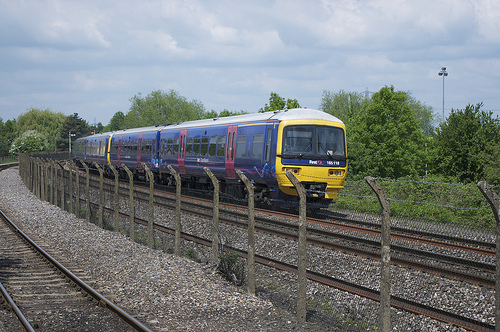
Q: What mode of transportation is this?
A: Train.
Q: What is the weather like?
A: Partly cloudy.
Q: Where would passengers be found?
A: Train cars.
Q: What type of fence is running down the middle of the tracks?
A: Chain link with barbed wire.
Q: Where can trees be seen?
A: Background.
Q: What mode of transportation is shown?
A: Train.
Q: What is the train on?
A: Tracks.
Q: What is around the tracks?
A: Gravel.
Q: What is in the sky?
A: Clouds.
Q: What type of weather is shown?
A: Cloudy.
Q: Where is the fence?
A: Between the tracks.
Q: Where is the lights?
A: Pole.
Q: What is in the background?
A: Trees.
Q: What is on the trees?
A: Leaves.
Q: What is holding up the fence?
A: Curved poles.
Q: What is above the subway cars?
A: Slightly cloudy skies.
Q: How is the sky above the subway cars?
A: White and blue.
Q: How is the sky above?
A: White and blue.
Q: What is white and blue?
A: The sky.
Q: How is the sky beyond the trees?
A: White and blue.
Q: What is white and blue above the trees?
A: The sky.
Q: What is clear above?
A: A blue and white sky.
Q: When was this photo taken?
A: Daytime.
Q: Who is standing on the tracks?
A: No one.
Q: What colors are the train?
A: Blue, Yellow, Red.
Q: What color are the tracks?
A: Brown.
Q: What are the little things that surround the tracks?
A: Rocks.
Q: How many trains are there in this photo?
A: One.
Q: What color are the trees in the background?
A: Green.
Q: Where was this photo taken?
A: Along a train track.